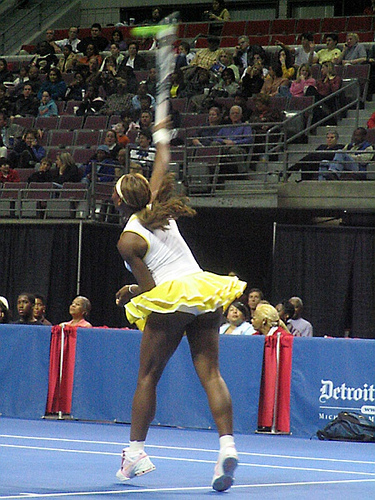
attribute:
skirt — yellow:
[121, 266, 250, 334]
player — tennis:
[109, 175, 218, 489]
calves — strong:
[206, 374, 233, 433]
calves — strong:
[133, 385, 153, 439]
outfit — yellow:
[109, 194, 252, 341]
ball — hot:
[130, 20, 155, 39]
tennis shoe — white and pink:
[114, 448, 156, 482]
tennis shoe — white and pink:
[210, 442, 239, 491]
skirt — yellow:
[108, 249, 285, 355]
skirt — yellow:
[121, 272, 253, 328]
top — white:
[116, 205, 201, 288]